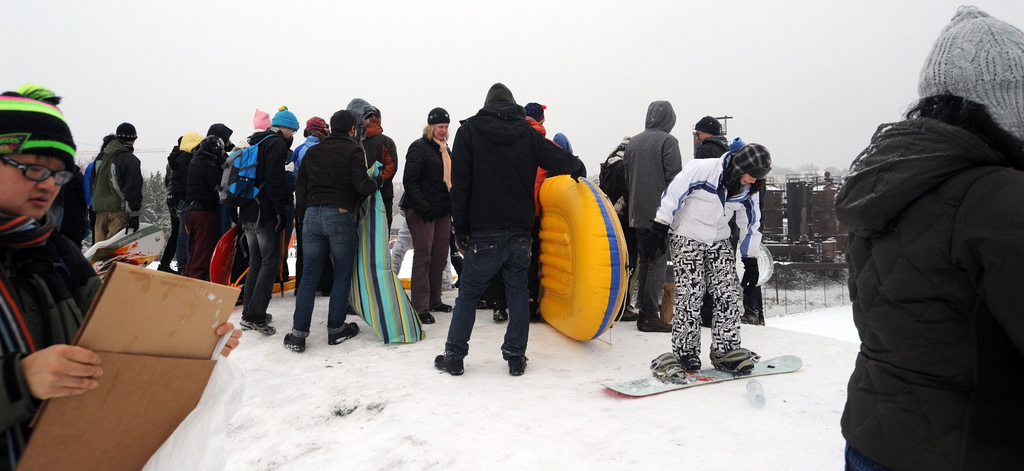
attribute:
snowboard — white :
[596, 341, 811, 406]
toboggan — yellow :
[536, 166, 628, 350]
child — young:
[230, 112, 303, 223]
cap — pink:
[248, 94, 291, 134]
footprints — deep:
[290, 373, 415, 465]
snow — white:
[215, 327, 833, 465]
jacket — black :
[462, 107, 546, 235]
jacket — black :
[405, 129, 451, 232]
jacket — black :
[861, 112, 1023, 468]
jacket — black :
[190, 135, 225, 213]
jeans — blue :
[288, 209, 388, 342]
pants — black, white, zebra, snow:
[662, 230, 755, 386]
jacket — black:
[849, 114, 1008, 466]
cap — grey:
[916, 8, 1019, 132]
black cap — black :
[0, 86, 86, 166]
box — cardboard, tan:
[80, 243, 246, 468]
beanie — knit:
[916, 4, 1022, 140]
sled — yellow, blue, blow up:
[521, 175, 653, 334]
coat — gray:
[624, 90, 675, 233]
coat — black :
[283, 115, 353, 226]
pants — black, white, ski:
[664, 231, 760, 369]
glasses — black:
[0, 156, 74, 192]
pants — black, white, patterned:
[401, 206, 621, 423]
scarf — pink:
[424, 131, 457, 198]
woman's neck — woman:
[420, 128, 450, 149]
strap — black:
[217, 130, 280, 221]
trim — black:
[227, 128, 273, 219]